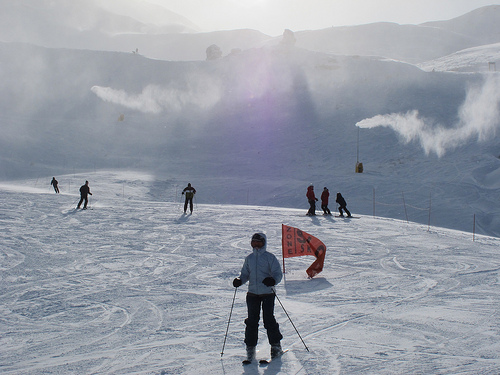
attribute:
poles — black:
[214, 288, 320, 360]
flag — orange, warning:
[278, 220, 327, 280]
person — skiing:
[161, 176, 231, 231]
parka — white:
[233, 245, 282, 296]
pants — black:
[247, 295, 281, 351]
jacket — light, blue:
[237, 233, 283, 294]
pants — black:
[246, 296, 282, 346]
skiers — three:
[305, 181, 355, 217]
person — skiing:
[76, 179, 93, 211]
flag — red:
[280, 221, 326, 278]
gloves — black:
[229, 275, 277, 288]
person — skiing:
[220, 229, 310, 365]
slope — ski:
[8, 190, 498, 373]